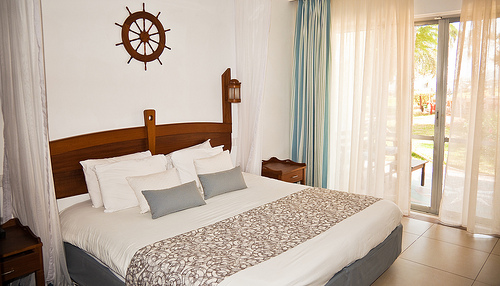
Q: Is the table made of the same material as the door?
A: No, the table is made of wood and the door is made of metal.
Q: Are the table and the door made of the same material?
A: No, the table is made of wood and the door is made of metal.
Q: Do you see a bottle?
A: No, there are no bottles.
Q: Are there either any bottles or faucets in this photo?
A: No, there are no bottles or faucets.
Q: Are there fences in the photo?
A: No, there are no fences.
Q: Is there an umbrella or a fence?
A: No, there are no fences or umbrellas.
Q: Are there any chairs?
A: Yes, there is a chair.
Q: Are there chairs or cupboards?
A: Yes, there is a chair.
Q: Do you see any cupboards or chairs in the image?
A: Yes, there is a chair.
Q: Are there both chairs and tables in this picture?
A: Yes, there are both a chair and a table.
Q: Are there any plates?
A: No, there are no plates.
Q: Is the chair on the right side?
A: Yes, the chair is on the right of the image.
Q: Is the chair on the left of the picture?
A: No, the chair is on the right of the image.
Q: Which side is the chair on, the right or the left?
A: The chair is on the right of the image.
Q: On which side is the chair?
A: The chair is on the right of the image.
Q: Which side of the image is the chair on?
A: The chair is on the right of the image.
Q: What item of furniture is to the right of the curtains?
A: The piece of furniture is a chair.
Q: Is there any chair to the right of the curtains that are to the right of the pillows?
A: Yes, there is a chair to the right of the curtains.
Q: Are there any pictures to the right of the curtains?
A: No, there is a chair to the right of the curtains.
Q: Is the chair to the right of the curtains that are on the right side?
A: Yes, the chair is to the right of the curtains.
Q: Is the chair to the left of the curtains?
A: No, the chair is to the right of the curtains.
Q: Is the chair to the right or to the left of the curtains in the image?
A: The chair is to the right of the curtains.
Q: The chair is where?
A: The chair is at the patio.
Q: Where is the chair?
A: The chair is at the patio.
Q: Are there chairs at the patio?
A: Yes, there is a chair at the patio.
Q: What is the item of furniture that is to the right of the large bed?
A: The piece of furniture is a chair.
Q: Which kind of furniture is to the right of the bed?
A: The piece of furniture is a chair.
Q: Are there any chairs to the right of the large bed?
A: Yes, there is a chair to the right of the bed.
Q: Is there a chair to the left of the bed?
A: No, the chair is to the right of the bed.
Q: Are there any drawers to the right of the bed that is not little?
A: No, there is a chair to the right of the bed.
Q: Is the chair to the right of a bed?
A: Yes, the chair is to the right of a bed.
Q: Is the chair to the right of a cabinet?
A: No, the chair is to the right of a bed.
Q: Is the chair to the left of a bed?
A: No, the chair is to the right of a bed.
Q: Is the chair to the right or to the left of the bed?
A: The chair is to the right of the bed.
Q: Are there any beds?
A: Yes, there is a bed.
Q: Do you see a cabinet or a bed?
A: Yes, there is a bed.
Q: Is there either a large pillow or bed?
A: Yes, there is a large bed.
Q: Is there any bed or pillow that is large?
A: Yes, the bed is large.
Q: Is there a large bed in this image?
A: Yes, there is a large bed.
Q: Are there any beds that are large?
A: Yes, there is a bed that is large.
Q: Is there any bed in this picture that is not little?
A: Yes, there is a large bed.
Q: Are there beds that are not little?
A: Yes, there is a large bed.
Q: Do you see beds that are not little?
A: Yes, there is a large bed.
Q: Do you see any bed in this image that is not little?
A: Yes, there is a large bed.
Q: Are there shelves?
A: No, there are no shelves.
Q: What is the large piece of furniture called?
A: The piece of furniture is a bed.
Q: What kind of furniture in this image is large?
A: The furniture is a bed.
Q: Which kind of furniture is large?
A: The furniture is a bed.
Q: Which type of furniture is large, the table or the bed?
A: The bed is large.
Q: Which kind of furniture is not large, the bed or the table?
A: The table is not large.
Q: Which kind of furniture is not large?
A: The furniture is a table.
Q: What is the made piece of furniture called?
A: The piece of furniture is a bed.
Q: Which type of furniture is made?
A: The furniture is a bed.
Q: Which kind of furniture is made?
A: The furniture is a bed.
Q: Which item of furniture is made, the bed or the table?
A: The bed is made.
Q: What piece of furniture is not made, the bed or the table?
A: The table is not made.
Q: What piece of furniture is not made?
A: The piece of furniture is a table.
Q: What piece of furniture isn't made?
A: The piece of furniture is a table.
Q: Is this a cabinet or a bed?
A: This is a bed.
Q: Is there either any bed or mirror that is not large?
A: No, there is a bed but it is large.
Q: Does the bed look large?
A: Yes, the bed is large.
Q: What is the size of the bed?
A: The bed is large.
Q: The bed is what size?
A: The bed is large.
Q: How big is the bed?
A: The bed is large.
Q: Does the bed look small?
A: No, the bed is large.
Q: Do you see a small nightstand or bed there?
A: No, there is a bed but it is large.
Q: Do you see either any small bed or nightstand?
A: No, there is a bed but it is large.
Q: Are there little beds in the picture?
A: No, there is a bed but it is large.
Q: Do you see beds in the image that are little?
A: No, there is a bed but it is large.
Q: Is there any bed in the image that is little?
A: No, there is a bed but it is large.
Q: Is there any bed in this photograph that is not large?
A: No, there is a bed but it is large.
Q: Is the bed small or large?
A: The bed is large.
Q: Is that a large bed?
A: Yes, that is a large bed.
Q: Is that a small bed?
A: No, that is a large bed.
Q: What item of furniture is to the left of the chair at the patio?
A: The piece of furniture is a bed.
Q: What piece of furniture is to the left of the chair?
A: The piece of furniture is a bed.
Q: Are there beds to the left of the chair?
A: Yes, there is a bed to the left of the chair.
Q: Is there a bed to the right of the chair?
A: No, the bed is to the left of the chair.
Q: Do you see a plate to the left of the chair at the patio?
A: No, there is a bed to the left of the chair.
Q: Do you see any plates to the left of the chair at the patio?
A: No, there is a bed to the left of the chair.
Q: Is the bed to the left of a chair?
A: Yes, the bed is to the left of a chair.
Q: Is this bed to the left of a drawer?
A: No, the bed is to the left of a chair.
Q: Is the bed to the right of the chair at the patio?
A: No, the bed is to the left of the chair.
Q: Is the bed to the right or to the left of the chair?
A: The bed is to the left of the chair.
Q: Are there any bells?
A: No, there are no bells.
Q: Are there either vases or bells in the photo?
A: No, there are no bells or vases.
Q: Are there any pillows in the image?
A: Yes, there are pillows.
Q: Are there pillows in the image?
A: Yes, there are pillows.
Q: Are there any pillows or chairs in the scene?
A: Yes, there are pillows.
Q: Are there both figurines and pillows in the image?
A: No, there are pillows but no figurines.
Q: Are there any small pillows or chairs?
A: Yes, there are small pillows.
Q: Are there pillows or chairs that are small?
A: Yes, the pillows are small.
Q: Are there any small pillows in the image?
A: Yes, there are small pillows.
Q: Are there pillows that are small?
A: Yes, there are pillows that are small.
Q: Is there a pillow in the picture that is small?
A: Yes, there are pillows that are small.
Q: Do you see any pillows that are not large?
A: Yes, there are small pillows.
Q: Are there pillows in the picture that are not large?
A: Yes, there are small pillows.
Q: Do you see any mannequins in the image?
A: No, there are no mannequins.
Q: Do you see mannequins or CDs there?
A: No, there are no mannequins or cds.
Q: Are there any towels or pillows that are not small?
A: No, there are pillows but they are small.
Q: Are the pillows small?
A: Yes, the pillows are small.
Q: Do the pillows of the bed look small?
A: Yes, the pillows are small.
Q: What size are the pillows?
A: The pillows are small.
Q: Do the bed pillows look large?
A: No, the pillows are small.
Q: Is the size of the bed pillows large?
A: No, the pillows are small.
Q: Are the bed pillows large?
A: No, the pillows are small.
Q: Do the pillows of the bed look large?
A: No, the pillows are small.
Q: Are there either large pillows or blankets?
A: No, there are pillows but they are small.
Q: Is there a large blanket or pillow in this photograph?
A: No, there are pillows but they are small.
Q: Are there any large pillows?
A: No, there are pillows but they are small.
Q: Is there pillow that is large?
A: No, there are pillows but they are small.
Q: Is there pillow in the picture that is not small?
A: No, there are pillows but they are small.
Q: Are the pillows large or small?
A: The pillows are small.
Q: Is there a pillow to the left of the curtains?
A: Yes, there are pillows to the left of the curtains.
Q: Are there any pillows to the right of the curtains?
A: No, the pillows are to the left of the curtains.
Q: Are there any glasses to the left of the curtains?
A: No, there are pillows to the left of the curtains.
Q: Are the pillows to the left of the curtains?
A: Yes, the pillows are to the left of the curtains.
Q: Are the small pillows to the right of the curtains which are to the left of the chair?
A: No, the pillows are to the left of the curtains.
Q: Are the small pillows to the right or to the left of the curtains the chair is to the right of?
A: The pillows are to the left of the curtains.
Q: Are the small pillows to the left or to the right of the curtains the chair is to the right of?
A: The pillows are to the left of the curtains.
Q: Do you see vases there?
A: No, there are no vases.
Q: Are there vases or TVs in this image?
A: No, there are no vases or tvs.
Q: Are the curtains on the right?
A: Yes, the curtains are on the right of the image.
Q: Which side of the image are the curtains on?
A: The curtains are on the right of the image.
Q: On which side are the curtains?
A: The curtains are on the right of the image.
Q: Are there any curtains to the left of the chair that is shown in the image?
A: Yes, there are curtains to the left of the chair.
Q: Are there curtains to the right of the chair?
A: No, the curtains are to the left of the chair.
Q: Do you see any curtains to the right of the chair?
A: No, the curtains are to the left of the chair.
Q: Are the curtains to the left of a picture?
A: No, the curtains are to the left of the chair.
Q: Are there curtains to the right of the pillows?
A: Yes, there are curtains to the right of the pillows.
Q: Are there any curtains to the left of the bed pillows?
A: No, the curtains are to the right of the pillows.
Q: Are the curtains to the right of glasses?
A: No, the curtains are to the right of the pillows.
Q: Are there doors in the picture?
A: Yes, there is a door.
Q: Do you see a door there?
A: Yes, there is a door.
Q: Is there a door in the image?
A: Yes, there is a door.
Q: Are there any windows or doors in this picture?
A: Yes, there is a door.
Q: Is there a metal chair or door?
A: Yes, there is a metal door.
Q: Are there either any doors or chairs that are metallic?
A: Yes, the door is metallic.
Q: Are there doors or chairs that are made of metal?
A: Yes, the door is made of metal.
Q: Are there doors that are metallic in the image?
A: Yes, there is a metal door.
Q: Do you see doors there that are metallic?
A: Yes, there is a door that is metallic.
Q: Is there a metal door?
A: Yes, there is a door that is made of metal.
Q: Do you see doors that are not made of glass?
A: Yes, there is a door that is made of metal.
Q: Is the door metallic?
A: Yes, the door is metallic.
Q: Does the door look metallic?
A: Yes, the door is metallic.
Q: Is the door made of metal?
A: Yes, the door is made of metal.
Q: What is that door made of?
A: The door is made of metal.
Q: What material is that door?
A: The door is made of metal.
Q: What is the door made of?
A: The door is made of metal.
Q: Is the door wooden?
A: No, the door is metallic.